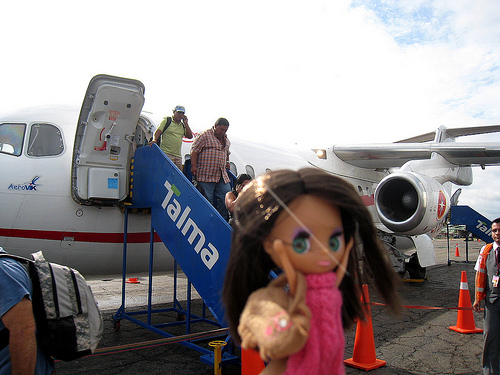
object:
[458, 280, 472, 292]
stripe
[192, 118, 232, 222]
man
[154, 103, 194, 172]
man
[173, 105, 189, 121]
head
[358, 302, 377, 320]
stripe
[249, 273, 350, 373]
dress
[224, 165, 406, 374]
childs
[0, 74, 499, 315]
airplane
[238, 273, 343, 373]
clothes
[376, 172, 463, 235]
engine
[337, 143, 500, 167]
wing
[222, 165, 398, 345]
dolls hair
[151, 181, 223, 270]
talma logo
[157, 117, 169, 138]
backpack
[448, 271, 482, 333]
orange cone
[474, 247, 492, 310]
orange vest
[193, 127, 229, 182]
checkered shirt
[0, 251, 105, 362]
black backpack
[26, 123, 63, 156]
windows of plane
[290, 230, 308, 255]
eye of the toy doll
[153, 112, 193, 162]
green shirt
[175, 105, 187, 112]
white hat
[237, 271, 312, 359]
cloth doll purse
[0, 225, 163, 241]
red stripe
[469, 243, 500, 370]
airport uniform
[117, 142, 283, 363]
airplane ladder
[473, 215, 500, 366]
an airport employee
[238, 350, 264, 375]
traffic cone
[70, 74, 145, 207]
an open door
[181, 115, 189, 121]
on a cell phone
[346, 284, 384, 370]
orange safety cone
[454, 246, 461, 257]
safety cone behind